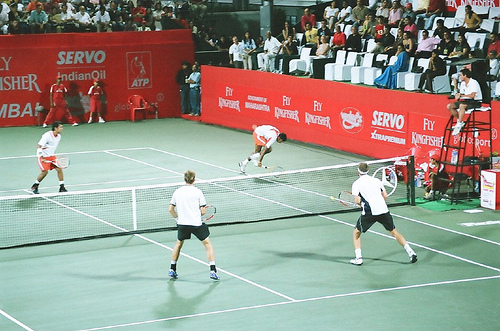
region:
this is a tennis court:
[60, 75, 355, 237]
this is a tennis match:
[64, 65, 341, 252]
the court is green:
[84, 110, 214, 202]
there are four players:
[65, 85, 392, 329]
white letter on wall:
[56, 48, 68, 66]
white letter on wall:
[64, 49, 74, 65]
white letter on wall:
[73, 50, 85, 64]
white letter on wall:
[82, 49, 97, 65]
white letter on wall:
[93, 48, 105, 68]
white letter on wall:
[28, 72, 42, 94]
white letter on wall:
[19, 73, 30, 93]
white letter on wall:
[9, 76, 21, 91]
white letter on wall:
[1, 73, 13, 92]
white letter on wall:
[6, 100, 23, 121]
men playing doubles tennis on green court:
[3, 112, 491, 324]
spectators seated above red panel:
[202, 7, 495, 167]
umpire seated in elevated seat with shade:
[430, 53, 495, 208]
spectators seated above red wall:
[3, 3, 195, 127]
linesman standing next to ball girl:
[40, 72, 107, 125]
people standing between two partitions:
[172, 57, 209, 121]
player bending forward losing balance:
[230, 120, 289, 180]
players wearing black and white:
[156, 158, 421, 284]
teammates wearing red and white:
[27, 119, 289, 194]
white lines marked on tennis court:
[6, 137, 495, 325]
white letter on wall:
[369, 108, 381, 127]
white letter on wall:
[375, 111, 386, 128]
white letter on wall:
[380, 110, 390, 127]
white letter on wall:
[65, 48, 75, 66]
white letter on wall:
[92, 50, 109, 67]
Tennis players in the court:
[150, 151, 409, 302]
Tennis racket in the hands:
[335, 177, 369, 221]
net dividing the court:
[2, 149, 421, 252]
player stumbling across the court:
[236, 119, 287, 179]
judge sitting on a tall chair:
[439, 65, 488, 138]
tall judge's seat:
[432, 54, 499, 203]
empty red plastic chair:
[118, 90, 156, 123]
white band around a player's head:
[356, 165, 373, 176]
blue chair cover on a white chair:
[376, 49, 410, 94]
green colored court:
[2, 116, 499, 329]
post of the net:
[406, 150, 418, 208]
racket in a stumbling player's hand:
[253, 161, 288, 180]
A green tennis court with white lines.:
[0, 116, 499, 328]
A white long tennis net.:
[0, 153, 412, 249]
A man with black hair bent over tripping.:
[240, 121, 287, 169]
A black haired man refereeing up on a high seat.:
[446, 69, 483, 135]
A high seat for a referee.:
[430, 55, 492, 207]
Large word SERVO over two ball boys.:
[56, 49, 106, 64]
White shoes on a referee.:
[450, 119, 465, 135]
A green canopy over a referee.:
[443, 58, 488, 65]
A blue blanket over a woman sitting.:
[372, 50, 409, 87]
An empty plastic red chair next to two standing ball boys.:
[127, 94, 147, 121]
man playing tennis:
[157, 158, 219, 300]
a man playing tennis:
[227, 108, 297, 191]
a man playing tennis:
[15, 109, 92, 209]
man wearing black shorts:
[145, 160, 242, 297]